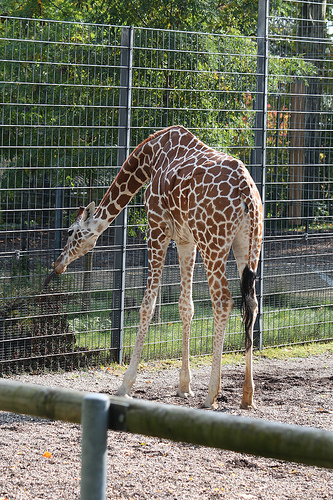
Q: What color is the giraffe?
A: Yellow and brown.